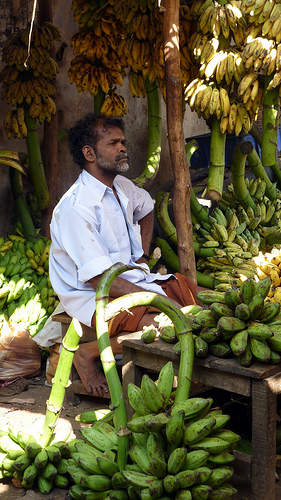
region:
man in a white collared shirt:
[44, 112, 204, 400]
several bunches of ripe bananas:
[180, 1, 279, 135]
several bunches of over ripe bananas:
[65, 3, 175, 122]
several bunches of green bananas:
[0, 225, 62, 335]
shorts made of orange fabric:
[88, 272, 205, 334]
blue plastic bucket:
[183, 124, 279, 170]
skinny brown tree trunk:
[153, 4, 208, 279]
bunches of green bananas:
[104, 363, 240, 498]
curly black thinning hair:
[63, 110, 120, 171]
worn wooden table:
[110, 320, 279, 491]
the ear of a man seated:
[82, 147, 97, 159]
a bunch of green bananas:
[141, 379, 170, 426]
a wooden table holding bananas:
[219, 361, 256, 384]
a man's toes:
[85, 384, 108, 394]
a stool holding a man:
[56, 315, 68, 325]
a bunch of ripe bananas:
[77, 68, 109, 86]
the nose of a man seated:
[118, 145, 127, 152]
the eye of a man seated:
[109, 141, 118, 147]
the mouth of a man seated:
[115, 157, 130, 163]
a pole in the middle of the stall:
[166, 122, 189, 207]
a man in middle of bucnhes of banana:
[0, 7, 277, 478]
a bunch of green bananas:
[125, 332, 239, 495]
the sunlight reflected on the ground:
[3, 408, 45, 432]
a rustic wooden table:
[120, 341, 275, 495]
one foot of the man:
[71, 344, 110, 396]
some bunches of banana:
[3, 0, 279, 134]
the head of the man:
[67, 113, 129, 174]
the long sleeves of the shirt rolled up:
[47, 177, 154, 284]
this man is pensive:
[50, 115, 231, 397]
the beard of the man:
[94, 146, 128, 171]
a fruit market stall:
[0, 0, 280, 498]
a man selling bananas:
[48, 112, 200, 396]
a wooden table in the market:
[116, 325, 279, 498]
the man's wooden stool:
[51, 311, 110, 405]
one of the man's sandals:
[0, 375, 28, 396]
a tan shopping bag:
[0, 321, 40, 380]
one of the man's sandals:
[26, 374, 46, 384]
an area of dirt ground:
[0, 383, 108, 498]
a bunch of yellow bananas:
[183, 78, 230, 118]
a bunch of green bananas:
[0, 317, 85, 493]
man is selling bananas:
[0, 2, 280, 498]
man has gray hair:
[45, 104, 156, 220]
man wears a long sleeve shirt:
[34, 105, 199, 345]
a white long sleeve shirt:
[45, 165, 175, 330]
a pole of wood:
[161, 0, 205, 293]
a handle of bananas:
[106, 288, 244, 498]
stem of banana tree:
[101, 291, 202, 388]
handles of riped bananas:
[62, 5, 161, 114]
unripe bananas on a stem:
[4, 371, 248, 498]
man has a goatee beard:
[60, 105, 141, 190]